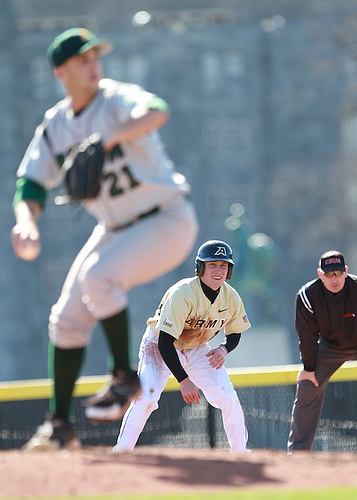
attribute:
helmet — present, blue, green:
[45, 24, 120, 77]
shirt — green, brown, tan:
[145, 286, 252, 349]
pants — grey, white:
[28, 210, 173, 321]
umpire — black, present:
[276, 247, 357, 484]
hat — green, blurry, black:
[318, 244, 352, 280]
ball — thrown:
[130, 10, 147, 24]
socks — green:
[28, 317, 144, 401]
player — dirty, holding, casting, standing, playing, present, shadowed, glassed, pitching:
[10, 41, 194, 273]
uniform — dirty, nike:
[128, 239, 222, 360]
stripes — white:
[293, 290, 331, 320]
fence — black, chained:
[19, 372, 355, 447]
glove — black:
[58, 145, 103, 186]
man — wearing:
[28, 30, 187, 109]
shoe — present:
[19, 417, 83, 459]